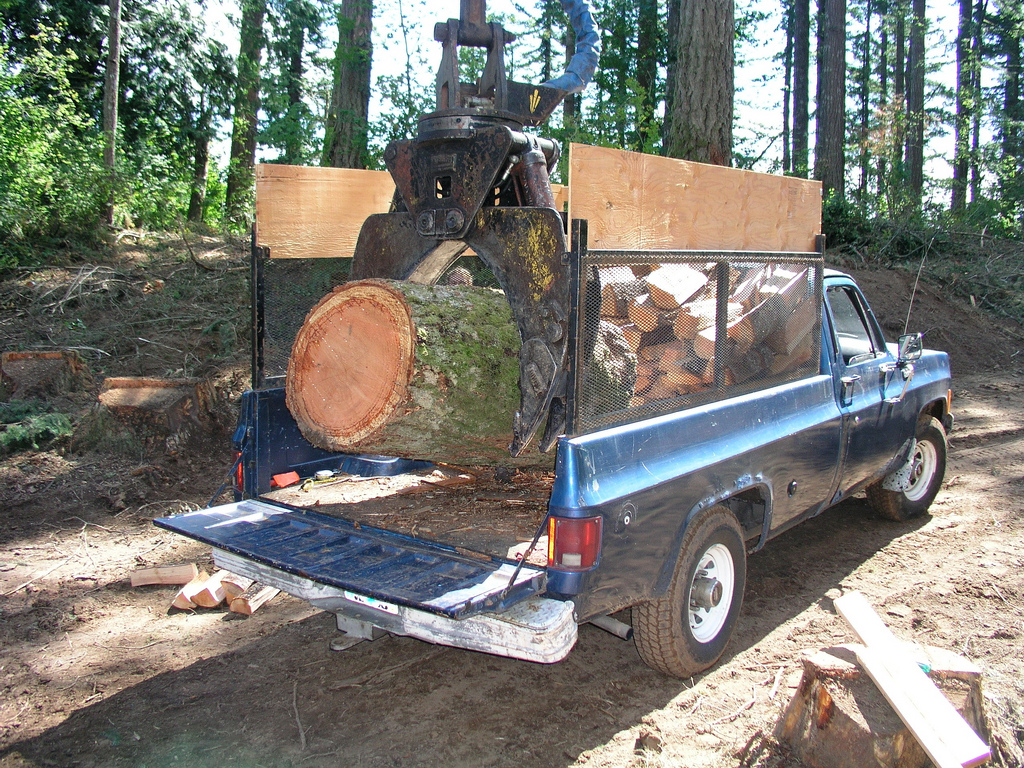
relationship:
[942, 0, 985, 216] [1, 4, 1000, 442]
tree in woods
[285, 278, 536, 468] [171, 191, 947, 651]
tree trunk on truck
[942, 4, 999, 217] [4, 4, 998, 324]
tree in woods